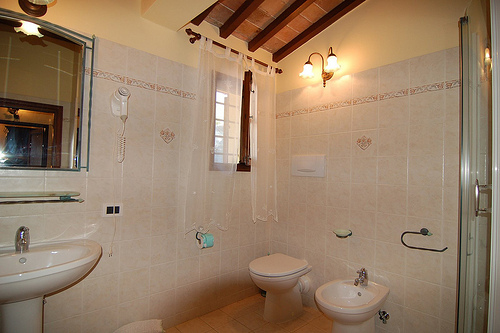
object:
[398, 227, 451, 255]
metal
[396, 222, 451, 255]
holder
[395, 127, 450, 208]
wall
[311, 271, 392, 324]
bidet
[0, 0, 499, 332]
bathroom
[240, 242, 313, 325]
toilet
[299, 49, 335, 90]
fixture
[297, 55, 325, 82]
bulbs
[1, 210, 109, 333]
sink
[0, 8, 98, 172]
mirror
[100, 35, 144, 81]
wall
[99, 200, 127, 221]
outlet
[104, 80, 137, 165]
dryer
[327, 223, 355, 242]
holder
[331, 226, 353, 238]
soap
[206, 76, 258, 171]
window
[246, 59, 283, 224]
curtains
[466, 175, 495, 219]
handle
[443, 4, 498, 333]
shower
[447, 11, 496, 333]
door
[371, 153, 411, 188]
tile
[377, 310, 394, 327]
valve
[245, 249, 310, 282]
seat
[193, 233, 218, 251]
paper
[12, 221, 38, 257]
faucet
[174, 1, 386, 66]
ceiling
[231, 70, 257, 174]
wood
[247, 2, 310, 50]
wood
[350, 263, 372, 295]
faucet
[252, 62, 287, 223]
lace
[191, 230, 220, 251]
dispenser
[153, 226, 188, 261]
wall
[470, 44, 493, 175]
glass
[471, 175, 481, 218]
silver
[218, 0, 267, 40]
beams